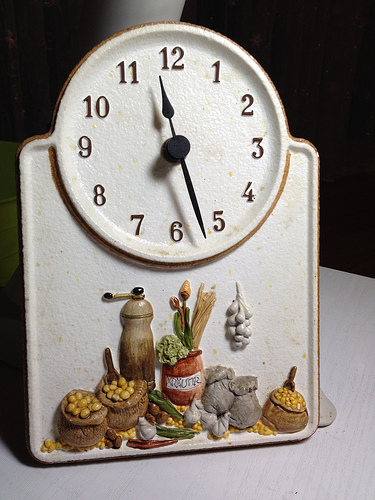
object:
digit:
[212, 60, 221, 83]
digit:
[171, 221, 184, 242]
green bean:
[148, 388, 184, 420]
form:
[2, 0, 375, 280]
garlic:
[227, 281, 253, 349]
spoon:
[283, 366, 297, 392]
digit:
[213, 211, 225, 232]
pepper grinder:
[102, 286, 156, 392]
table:
[0, 265, 374, 499]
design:
[41, 279, 309, 453]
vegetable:
[154, 334, 188, 366]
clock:
[49, 21, 291, 269]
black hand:
[180, 158, 207, 239]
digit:
[131, 214, 145, 235]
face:
[65, 43, 276, 246]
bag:
[260, 389, 309, 433]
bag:
[57, 388, 108, 446]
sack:
[203, 365, 234, 416]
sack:
[229, 375, 263, 430]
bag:
[96, 375, 149, 431]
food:
[274, 388, 307, 411]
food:
[103, 377, 135, 401]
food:
[66, 392, 102, 418]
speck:
[229, 171, 232, 177]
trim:
[275, 148, 291, 206]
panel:
[17, 137, 320, 465]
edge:
[18, 164, 41, 443]